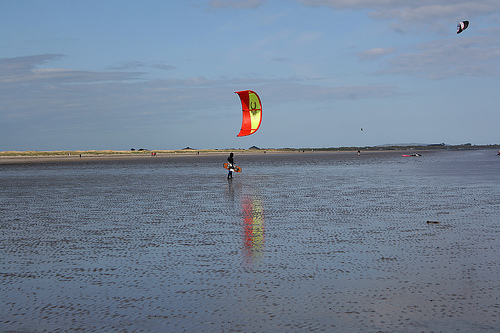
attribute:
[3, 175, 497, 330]
ocean. — big, blue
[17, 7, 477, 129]
sky — cloudy 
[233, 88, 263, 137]
kite — red, yellow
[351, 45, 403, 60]
cloud — big, fluffy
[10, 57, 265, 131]
clouds — thin 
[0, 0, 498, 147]
sky — blue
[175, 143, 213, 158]
dune — sand 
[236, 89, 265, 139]
kite — orange, red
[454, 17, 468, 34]
kite — black, white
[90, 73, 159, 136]
clouds — grey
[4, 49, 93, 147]
clouds — grey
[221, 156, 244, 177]
surfboard — orange, white